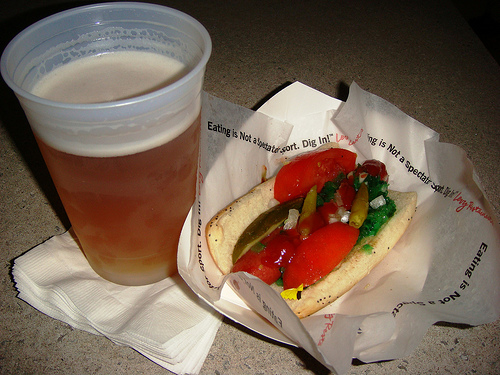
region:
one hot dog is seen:
[104, 288, 196, 348]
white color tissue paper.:
[86, 293, 176, 329]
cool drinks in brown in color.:
[48, 124, 172, 247]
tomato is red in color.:
[286, 157, 349, 172]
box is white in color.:
[224, 297, 271, 339]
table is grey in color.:
[288, 38, 403, 75]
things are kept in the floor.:
[20, 155, 349, 349]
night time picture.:
[18, 34, 499, 299]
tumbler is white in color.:
[11, 14, 203, 121]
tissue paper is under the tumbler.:
[58, 210, 207, 325]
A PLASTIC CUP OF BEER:
[2, 3, 217, 291]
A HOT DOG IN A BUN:
[198, 136, 421, 327]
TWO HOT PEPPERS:
[289, 178, 388, 240]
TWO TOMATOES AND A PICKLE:
[221, 146, 372, 293]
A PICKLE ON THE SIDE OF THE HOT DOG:
[224, 176, 338, 268]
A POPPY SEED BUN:
[199, 134, 427, 322]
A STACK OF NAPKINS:
[8, 229, 239, 374]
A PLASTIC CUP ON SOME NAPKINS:
[6, 5, 221, 360]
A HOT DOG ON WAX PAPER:
[175, 76, 467, 354]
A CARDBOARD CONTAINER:
[166, 71, 452, 358]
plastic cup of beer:
[6, 1, 201, 304]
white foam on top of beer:
[26, 41, 199, 145]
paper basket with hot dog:
[190, 73, 461, 358]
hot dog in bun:
[209, 137, 424, 319]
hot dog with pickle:
[215, 140, 421, 319]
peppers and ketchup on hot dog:
[277, 144, 392, 299]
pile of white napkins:
[10, 197, 224, 365]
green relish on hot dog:
[298, 147, 392, 239]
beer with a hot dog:
[18, 5, 479, 363]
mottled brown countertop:
[237, 25, 483, 150]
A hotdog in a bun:
[206, 138, 419, 316]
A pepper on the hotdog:
[344, 180, 374, 235]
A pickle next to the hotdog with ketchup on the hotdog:
[230, 190, 301, 279]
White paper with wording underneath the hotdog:
[193, 81, 498, 373]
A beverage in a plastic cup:
[1, 0, 212, 294]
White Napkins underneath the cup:
[12, 226, 227, 373]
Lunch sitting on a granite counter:
[0, 0, 498, 373]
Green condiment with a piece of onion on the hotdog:
[361, 180, 396, 247]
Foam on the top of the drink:
[13, 42, 200, 156]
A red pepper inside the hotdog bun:
[284, 223, 359, 288]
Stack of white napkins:
[29, 256, 165, 371]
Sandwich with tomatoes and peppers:
[214, 131, 394, 332]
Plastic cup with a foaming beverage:
[3, 43, 200, 277]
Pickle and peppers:
[244, 194, 359, 281]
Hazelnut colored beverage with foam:
[20, 43, 182, 284]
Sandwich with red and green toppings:
[207, 121, 404, 343]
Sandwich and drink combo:
[14, 11, 496, 373]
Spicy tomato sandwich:
[232, 126, 416, 355]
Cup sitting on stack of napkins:
[2, 8, 217, 360]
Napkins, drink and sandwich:
[4, 6, 468, 369]